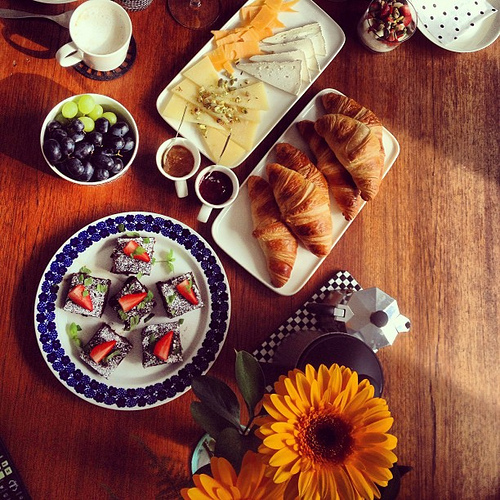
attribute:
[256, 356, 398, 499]
flower — large, sunflower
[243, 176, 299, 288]
bread — crispy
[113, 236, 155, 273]
brownie — square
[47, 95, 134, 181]
grapes — purple, green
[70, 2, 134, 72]
mug — white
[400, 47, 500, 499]
table — full, wood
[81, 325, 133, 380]
brownie — sugared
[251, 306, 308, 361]
napkin — plaid, checkered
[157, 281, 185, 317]
brownie — sugared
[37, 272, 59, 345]
trim — blue